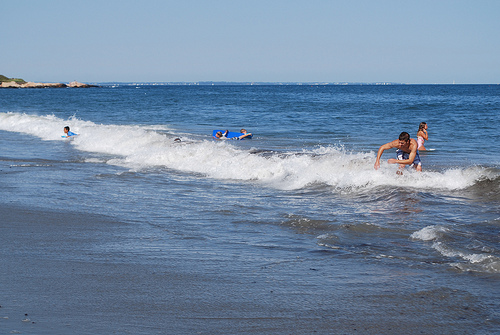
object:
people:
[238, 129, 254, 139]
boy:
[214, 130, 231, 140]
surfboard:
[212, 130, 244, 141]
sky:
[0, 0, 499, 95]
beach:
[1, 80, 500, 334]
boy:
[63, 125, 79, 136]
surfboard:
[62, 136, 66, 138]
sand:
[1, 78, 89, 87]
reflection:
[383, 180, 438, 214]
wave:
[0, 108, 499, 277]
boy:
[373, 132, 423, 171]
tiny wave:
[409, 224, 499, 263]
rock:
[0, 82, 20, 89]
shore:
[19, 184, 148, 333]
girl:
[416, 122, 428, 151]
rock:
[20, 80, 46, 87]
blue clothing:
[238, 133, 254, 140]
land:
[0, 74, 89, 88]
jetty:
[0, 77, 96, 88]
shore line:
[46, 220, 148, 242]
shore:
[235, 250, 338, 308]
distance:
[8, 56, 96, 96]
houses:
[65, 81, 91, 89]